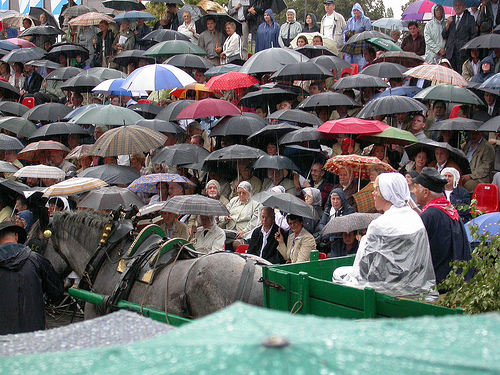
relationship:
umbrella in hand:
[147, 190, 229, 225] [184, 220, 203, 241]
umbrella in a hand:
[299, 89, 349, 110] [292, 87, 317, 107]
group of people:
[10, 7, 480, 225] [4, 9, 470, 228]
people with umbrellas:
[4, 9, 470, 228] [3, 30, 481, 168]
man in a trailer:
[408, 165, 474, 295] [259, 249, 462, 321]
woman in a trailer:
[330, 171, 439, 306] [259, 249, 462, 321]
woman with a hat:
[330, 171, 439, 306] [235, 179, 250, 191]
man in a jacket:
[0, 220, 65, 337] [0, 246, 54, 320]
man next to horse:
[0, 220, 65, 337] [27, 197, 260, 312]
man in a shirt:
[246, 204, 282, 254] [260, 230, 271, 254]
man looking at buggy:
[246, 204, 282, 254] [260, 248, 443, 311]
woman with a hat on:
[328, 166, 432, 287] [379, 171, 409, 203]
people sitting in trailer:
[272, 213, 317, 262] [259, 246, 449, 316]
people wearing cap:
[272, 213, 317, 262] [378, 170, 410, 204]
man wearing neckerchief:
[408, 165, 474, 295] [423, 198, 460, 219]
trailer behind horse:
[259, 246, 449, 316] [21, 207, 276, 323]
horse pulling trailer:
[21, 207, 276, 323] [256, 249, 448, 313]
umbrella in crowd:
[120, 56, 192, 95] [5, 5, 464, 235]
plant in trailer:
[438, 223, 483, 311] [259, 246, 449, 316]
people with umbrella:
[272, 213, 317, 262] [152, 188, 234, 228]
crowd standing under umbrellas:
[4, 4, 498, 322] [4, 2, 498, 325]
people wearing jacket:
[272, 213, 317, 262] [255, 7, 284, 50]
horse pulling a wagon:
[21, 207, 276, 323] [57, 218, 498, 323]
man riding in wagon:
[410, 162, 477, 294] [75, 249, 498, 341]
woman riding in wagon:
[330, 171, 439, 306] [75, 249, 498, 341]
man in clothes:
[1, 216, 79, 346] [4, 244, 62, 336]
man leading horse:
[1, 216, 79, 346] [28, 198, 284, 334]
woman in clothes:
[330, 171, 439, 306] [339, 214, 433, 299]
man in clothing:
[408, 165, 474, 295] [422, 202, 476, 298]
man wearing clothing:
[408, 165, 474, 295] [422, 202, 476, 298]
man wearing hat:
[408, 165, 474, 295] [408, 167, 451, 196]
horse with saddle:
[30, 207, 273, 327] [102, 200, 198, 278]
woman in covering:
[330, 171, 439, 306] [344, 211, 442, 307]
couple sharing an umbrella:
[246, 209, 318, 278] [246, 187, 315, 223]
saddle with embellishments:
[97, 202, 191, 283] [84, 216, 194, 292]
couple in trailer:
[342, 160, 480, 305] [259, 249, 462, 321]